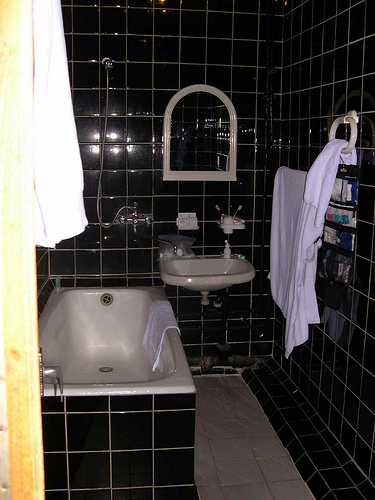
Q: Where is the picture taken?
A: A bathroom.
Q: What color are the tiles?
A: Black.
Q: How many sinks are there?
A: One.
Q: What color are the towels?
A: White.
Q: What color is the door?
A: Brown.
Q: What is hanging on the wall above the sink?
A: A mirror.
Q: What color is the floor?
A: Gray.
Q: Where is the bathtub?
A: On the left.